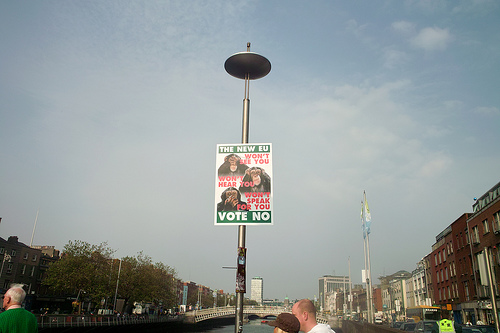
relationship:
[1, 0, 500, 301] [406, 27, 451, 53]
sky has cloud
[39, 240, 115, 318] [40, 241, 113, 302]
tree has leaves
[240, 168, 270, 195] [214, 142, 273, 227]
monkey on poster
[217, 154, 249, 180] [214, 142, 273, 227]
monkey on a poster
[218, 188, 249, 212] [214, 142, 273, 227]
monkey on a poster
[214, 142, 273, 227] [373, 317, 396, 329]
poster on street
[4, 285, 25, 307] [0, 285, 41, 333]
head of man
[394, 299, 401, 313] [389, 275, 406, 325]
sign outside building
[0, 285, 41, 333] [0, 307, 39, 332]
man in sweater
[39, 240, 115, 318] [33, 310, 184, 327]
tree growing on street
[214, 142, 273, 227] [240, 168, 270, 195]
poster with monkey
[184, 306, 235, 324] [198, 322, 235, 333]
bridge over a river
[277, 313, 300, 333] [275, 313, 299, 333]
woman wearing hat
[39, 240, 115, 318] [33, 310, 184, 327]
tree lining street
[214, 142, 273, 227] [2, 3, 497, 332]
poster in middle of city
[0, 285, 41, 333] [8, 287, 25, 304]
man has white hair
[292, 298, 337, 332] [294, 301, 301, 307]
man has a receding hairline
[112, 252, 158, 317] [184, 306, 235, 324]
tree near bridge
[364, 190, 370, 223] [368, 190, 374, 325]
flag on flagpole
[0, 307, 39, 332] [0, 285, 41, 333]
sweater on man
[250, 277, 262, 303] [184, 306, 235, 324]
skyscraper behind bridge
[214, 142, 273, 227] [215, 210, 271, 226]
sign says vote no